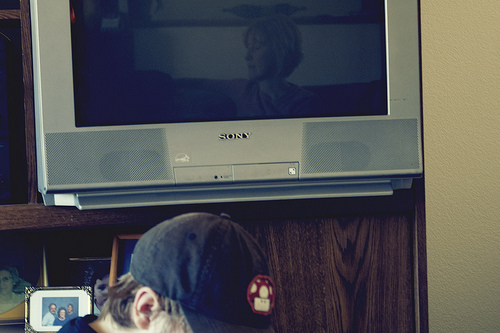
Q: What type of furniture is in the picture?
A: The furniture is an entertainment center.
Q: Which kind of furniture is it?
A: The piece of furniture is an entertainment center.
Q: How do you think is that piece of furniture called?
A: This is an entertainment center.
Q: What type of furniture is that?
A: This is an entertainment center.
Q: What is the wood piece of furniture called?
A: The piece of furniture is an entertainment center.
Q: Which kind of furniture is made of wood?
A: The furniture is an entertainment center.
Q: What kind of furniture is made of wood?
A: The furniture is an entertainment center.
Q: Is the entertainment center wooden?
A: Yes, the entertainment center is wooden.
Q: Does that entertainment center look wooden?
A: Yes, the entertainment center is wooden.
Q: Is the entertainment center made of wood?
A: Yes, the entertainment center is made of wood.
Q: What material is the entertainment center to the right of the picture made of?
A: The entertainment center is made of wood.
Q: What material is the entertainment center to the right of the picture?
A: The entertainment center is made of wood.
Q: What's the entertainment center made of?
A: The entertainment center is made of wood.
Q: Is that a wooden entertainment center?
A: Yes, that is a wooden entertainment center.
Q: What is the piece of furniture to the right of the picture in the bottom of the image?
A: The piece of furniture is an entertainment center.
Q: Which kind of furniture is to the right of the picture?
A: The piece of furniture is an entertainment center.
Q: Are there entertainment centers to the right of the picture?
A: Yes, there is an entertainment center to the right of the picture.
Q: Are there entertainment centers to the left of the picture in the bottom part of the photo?
A: No, the entertainment center is to the right of the picture.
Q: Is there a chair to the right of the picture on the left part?
A: No, there is an entertainment center to the right of the picture.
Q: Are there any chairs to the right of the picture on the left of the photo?
A: No, there is an entertainment center to the right of the picture.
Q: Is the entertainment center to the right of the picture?
A: Yes, the entertainment center is to the right of the picture.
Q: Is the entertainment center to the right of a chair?
A: No, the entertainment center is to the right of the picture.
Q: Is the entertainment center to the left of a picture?
A: No, the entertainment center is to the right of a picture.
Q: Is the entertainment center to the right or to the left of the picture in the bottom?
A: The entertainment center is to the right of the picture.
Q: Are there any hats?
A: Yes, there is a hat.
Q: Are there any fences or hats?
A: Yes, there is a hat.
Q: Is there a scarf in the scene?
A: No, there are no scarves.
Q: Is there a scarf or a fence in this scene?
A: No, there are no scarves or fences.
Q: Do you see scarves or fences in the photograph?
A: No, there are no scarves or fences.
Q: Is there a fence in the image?
A: No, there are no fences.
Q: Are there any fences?
A: No, there are no fences.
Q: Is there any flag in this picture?
A: No, there are no flags.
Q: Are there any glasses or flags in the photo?
A: No, there are no flags or glasses.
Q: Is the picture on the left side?
A: Yes, the picture is on the left of the image.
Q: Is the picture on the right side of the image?
A: No, the picture is on the left of the image.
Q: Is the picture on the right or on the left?
A: The picture is on the left of the image.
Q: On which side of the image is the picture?
A: The picture is on the left of the image.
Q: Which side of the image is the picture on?
A: The picture is on the left of the image.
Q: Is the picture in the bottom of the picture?
A: Yes, the picture is in the bottom of the image.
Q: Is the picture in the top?
A: No, the picture is in the bottom of the image.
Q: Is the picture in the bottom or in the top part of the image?
A: The picture is in the bottom of the image.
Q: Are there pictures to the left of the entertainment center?
A: Yes, there is a picture to the left of the entertainment center.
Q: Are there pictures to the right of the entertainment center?
A: No, the picture is to the left of the entertainment center.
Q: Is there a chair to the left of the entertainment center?
A: No, there is a picture to the left of the entertainment center.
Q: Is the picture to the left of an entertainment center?
A: Yes, the picture is to the left of an entertainment center.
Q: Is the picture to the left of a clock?
A: No, the picture is to the left of an entertainment center.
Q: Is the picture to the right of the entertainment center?
A: No, the picture is to the left of the entertainment center.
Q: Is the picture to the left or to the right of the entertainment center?
A: The picture is to the left of the entertainment center.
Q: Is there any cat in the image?
A: No, there are no cats.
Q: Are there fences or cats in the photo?
A: No, there are no cats or fences.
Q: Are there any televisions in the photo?
A: Yes, there is a television.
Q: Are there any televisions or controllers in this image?
A: Yes, there is a television.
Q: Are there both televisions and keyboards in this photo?
A: No, there is a television but no keyboards.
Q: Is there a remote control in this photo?
A: No, there are no remote controls.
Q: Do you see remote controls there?
A: No, there are no remote controls.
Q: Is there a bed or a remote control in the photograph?
A: No, there are no remote controls or beds.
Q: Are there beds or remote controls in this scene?
A: No, there are no remote controls or beds.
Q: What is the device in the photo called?
A: The device is a television.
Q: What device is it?
A: The device is a television.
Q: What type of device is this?
A: That is a television.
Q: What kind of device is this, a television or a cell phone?
A: That is a television.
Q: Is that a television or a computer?
A: That is a television.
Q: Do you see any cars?
A: No, there are no cars.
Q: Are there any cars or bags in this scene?
A: No, there are no cars or bags.